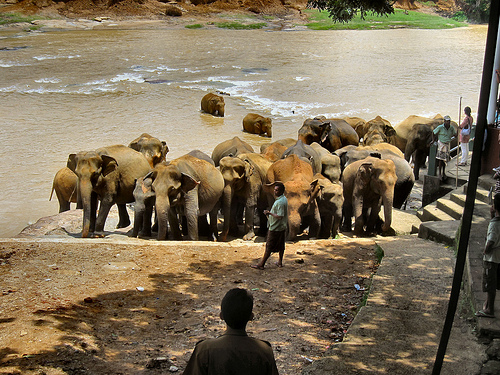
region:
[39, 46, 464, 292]
a group of elephants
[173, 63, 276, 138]
two elephants in the river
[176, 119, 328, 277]
a guy wearing shorts in front of the elephants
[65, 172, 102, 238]
a brown trunk of an elephant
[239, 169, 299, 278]
a guy wearing shorts and polo shirt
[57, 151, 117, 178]
big and floppy ears of an elephant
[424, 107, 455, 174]
a guy wearing a hat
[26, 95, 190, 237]
group of elephants at the river bank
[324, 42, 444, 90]
muddy colored river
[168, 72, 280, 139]
two elephants with trunks in the water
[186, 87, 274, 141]
elephants half way submerged in water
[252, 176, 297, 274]
man standing in front of heard of elephants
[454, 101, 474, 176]
woman standing on dock in front of water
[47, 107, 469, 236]
group of elephants at the edge of the water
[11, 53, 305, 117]
mild river rapids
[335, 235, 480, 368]
cement walkway leading to the water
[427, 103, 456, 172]
man in teal shirt with his back to the elephants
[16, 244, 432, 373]
shadows from trees cast across the beach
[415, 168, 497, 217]
cement steps leading up to dock in front of water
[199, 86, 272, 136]
elephants walking up to large group of elephants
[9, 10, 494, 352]
elephants on a shoreline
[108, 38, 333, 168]
these elephants might be crossing the river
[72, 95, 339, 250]
this man is standing by the elephants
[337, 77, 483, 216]
these people might be herding the elephants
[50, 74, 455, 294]
the elephants are standing on the shore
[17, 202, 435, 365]
the ground is muddy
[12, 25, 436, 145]
the water looks murky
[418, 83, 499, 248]
the people are standing on some kind of dock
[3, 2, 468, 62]
the other side of the river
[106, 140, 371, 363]
the guy is watching the elephants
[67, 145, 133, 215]
large elephant near water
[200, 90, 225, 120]
elephant walking in water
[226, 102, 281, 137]
brown elephant in water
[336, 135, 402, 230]
brown elephant next to stairs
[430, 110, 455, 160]
man wearing a green shirt and hat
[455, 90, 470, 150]
woman wearing pink shirt and white pants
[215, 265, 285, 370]
man wearing a brown shirt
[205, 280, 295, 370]
man looking at elephants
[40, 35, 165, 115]
lake with elephants in it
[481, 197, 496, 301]
man looking at elephants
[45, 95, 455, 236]
twenty-two elephants leaving a river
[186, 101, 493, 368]
five people at a river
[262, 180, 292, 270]
man wearing white shirt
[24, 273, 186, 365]
shadows from the trees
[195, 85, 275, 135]
two elephants walking across a river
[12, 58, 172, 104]
water foaming across the rocks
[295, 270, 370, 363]
garbage gathered on the ground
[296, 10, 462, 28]
grassy area across the river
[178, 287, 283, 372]
man watching the elephants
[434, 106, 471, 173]
two people talking near the elephants